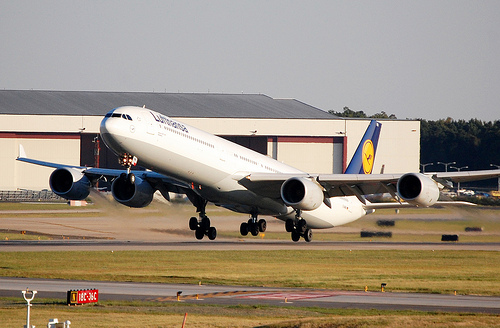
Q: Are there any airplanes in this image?
A: Yes, there is an airplane.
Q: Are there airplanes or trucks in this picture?
A: Yes, there is an airplane.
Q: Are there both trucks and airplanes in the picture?
A: No, there is an airplane but no trucks.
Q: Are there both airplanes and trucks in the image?
A: No, there is an airplane but no trucks.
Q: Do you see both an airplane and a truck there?
A: No, there is an airplane but no trucks.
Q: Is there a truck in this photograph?
A: No, there are no trucks.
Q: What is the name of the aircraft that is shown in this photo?
A: The aircraft is an airplane.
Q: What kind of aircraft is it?
A: The aircraft is an airplane.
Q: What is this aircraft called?
A: This is an airplane.